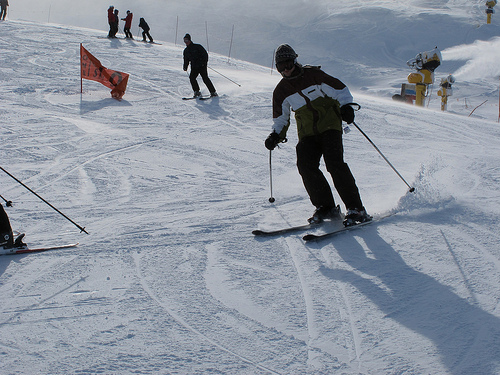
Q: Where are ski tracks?
A: On the snow.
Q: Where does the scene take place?
A: On a ski slope.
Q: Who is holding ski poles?
A: The skiers.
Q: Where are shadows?
A: On the snow.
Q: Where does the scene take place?
A: On a ski slope.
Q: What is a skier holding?
A: Ski poles.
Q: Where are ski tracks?
A: On the snow.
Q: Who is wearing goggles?
A: The skier.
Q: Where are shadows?
A: On the snow.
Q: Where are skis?
A: Under skiers feet.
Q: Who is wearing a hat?
A: The skier.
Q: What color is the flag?
A: Red.